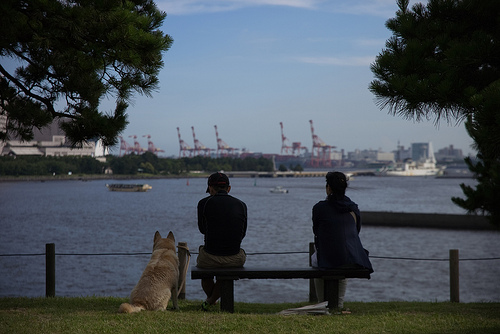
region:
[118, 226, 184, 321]
a dog sitting the ground by a lake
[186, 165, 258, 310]
a man sitting on a bench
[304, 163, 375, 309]
a man sitting on a bench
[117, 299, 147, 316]
the tail of a dog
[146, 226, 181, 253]
the head of a dog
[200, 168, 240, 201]
the head of a man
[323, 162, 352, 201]
the head of a man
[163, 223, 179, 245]
the ear of a dog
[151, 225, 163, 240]
the ear of a dog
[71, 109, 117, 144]
the leaves of a tree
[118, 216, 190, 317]
gray dog sitting in green grass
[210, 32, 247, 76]
white clouds in blue sky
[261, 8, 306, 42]
white clouds in blue sky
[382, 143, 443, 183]
white boat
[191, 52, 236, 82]
white clouds in blue sky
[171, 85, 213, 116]
white clouds in blue sky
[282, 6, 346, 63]
white clouds in blue sky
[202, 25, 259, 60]
white clouds in blue sky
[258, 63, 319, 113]
white clouds in blue sky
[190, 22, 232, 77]
white clouds in blue sky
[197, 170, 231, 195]
Man wearing a dark baseball cap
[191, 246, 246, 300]
Pair of khaki colored pants being worn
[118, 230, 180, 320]
Light colored dog with it's two ears perked up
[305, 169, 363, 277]
Person wearing a light blue jacket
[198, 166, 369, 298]
Two people sitting on the ends of a small black bench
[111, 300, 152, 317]
Fluffy yellow tail of a dog on the grass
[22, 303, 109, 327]
Short patch of green grass with visible brown dirt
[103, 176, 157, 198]
Small tan colored boat in blue water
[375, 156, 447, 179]
Large white colored ship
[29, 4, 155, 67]
Thick and dark green leaves of a tree on firm branches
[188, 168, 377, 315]
two people sitting on a bench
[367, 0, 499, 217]
evergreen trees extending out on a strip of land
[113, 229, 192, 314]
dog with leash tied to a pole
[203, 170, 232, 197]
man wearing a baseball cap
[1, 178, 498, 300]
body of water in front of couple on a bench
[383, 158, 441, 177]
white ship at the dock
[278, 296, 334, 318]
newspaper on the ground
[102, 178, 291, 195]
boats on the water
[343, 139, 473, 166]
buildings in the background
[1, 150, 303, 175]
trees on the other side of the water